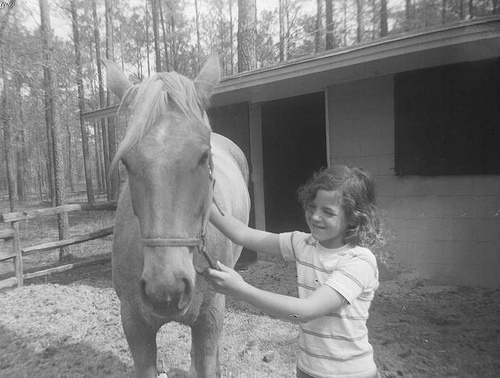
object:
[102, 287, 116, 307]
imprints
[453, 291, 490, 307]
dirt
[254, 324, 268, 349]
imprints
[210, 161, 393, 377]
child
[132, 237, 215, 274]
mouth strap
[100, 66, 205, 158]
hair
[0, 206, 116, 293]
wooden fence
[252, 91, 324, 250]
stall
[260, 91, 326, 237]
door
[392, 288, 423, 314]
small imprints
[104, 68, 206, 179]
mane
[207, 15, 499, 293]
building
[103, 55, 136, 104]
ears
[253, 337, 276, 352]
imprint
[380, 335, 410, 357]
imprint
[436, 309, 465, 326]
imprint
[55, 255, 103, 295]
dirt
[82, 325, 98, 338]
imprint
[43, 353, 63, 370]
imprint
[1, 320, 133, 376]
shadow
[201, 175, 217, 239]
rope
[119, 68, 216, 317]
face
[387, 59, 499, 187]
board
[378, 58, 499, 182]
window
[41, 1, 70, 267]
trunk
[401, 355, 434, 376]
dirt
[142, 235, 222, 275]
halter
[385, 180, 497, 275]
shingle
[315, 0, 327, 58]
trees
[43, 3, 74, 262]
trees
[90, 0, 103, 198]
trees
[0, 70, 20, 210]
trees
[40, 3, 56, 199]
trees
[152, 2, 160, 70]
trees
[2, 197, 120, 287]
fence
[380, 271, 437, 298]
shadow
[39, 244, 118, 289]
shadow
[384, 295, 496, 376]
shadow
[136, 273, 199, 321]
horse's nose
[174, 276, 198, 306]
nostril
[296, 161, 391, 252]
hair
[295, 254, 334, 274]
stripe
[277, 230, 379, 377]
shirt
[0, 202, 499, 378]
ground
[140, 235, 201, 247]
strap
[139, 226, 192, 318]
mouth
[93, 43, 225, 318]
head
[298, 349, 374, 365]
stripes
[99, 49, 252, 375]
horse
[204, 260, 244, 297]
hand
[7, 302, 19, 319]
imprints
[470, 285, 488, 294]
imprints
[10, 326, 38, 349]
dirt